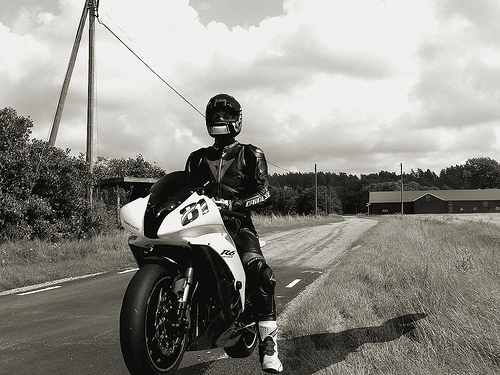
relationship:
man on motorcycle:
[186, 92, 268, 193] [119, 170, 263, 373]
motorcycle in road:
[119, 170, 263, 373] [272, 226, 342, 285]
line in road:
[26, 273, 75, 305] [272, 226, 342, 285]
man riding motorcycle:
[186, 92, 268, 193] [119, 170, 263, 373]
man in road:
[186, 92, 268, 193] [272, 226, 342, 285]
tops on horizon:
[12, 109, 480, 180] [5, 82, 484, 167]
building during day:
[372, 175, 482, 218] [14, 4, 484, 189]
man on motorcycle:
[186, 92, 268, 193] [119, 176, 268, 371]